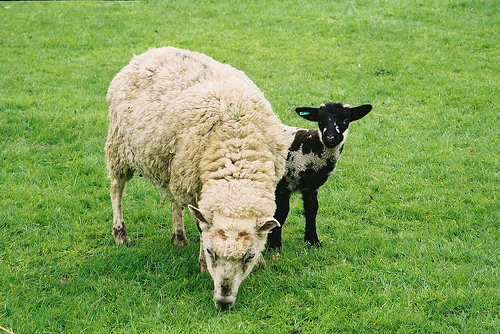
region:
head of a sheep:
[169, 191, 289, 322]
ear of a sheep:
[175, 185, 213, 231]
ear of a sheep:
[239, 204, 296, 241]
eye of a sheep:
[193, 240, 216, 267]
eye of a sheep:
[240, 242, 260, 260]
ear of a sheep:
[291, 107, 318, 129]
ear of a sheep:
[354, 96, 374, 121]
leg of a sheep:
[250, 178, 307, 260]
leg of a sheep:
[93, 181, 147, 258]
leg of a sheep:
[294, 187, 329, 247]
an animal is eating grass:
[93, 42, 293, 316]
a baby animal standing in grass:
[261, 91, 383, 265]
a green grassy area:
[373, 10, 490, 332]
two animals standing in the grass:
[93, 43, 375, 318]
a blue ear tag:
[294, 107, 311, 118]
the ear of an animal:
[349, 98, 374, 123]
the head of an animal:
[186, 197, 290, 313]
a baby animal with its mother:
[90, 41, 373, 315]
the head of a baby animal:
[291, 94, 374, 147]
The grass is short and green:
[376, 35, 481, 304]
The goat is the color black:
[287, 73, 375, 260]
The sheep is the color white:
[87, 38, 292, 310]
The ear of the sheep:
[181, 199, 216, 230]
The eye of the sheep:
[199, 242, 224, 264]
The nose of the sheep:
[210, 291, 240, 312]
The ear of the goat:
[295, 99, 322, 124]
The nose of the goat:
[321, 128, 338, 146]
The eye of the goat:
[339, 113, 352, 130]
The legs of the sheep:
[101, 178, 188, 252]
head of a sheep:
[166, 185, 301, 312]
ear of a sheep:
[188, 201, 225, 229]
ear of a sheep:
[246, 204, 294, 244]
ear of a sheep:
[280, 93, 327, 160]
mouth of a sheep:
[314, 124, 342, 151]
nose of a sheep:
[211, 265, 256, 291]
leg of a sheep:
[163, 179, 205, 245]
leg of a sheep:
[258, 188, 294, 262]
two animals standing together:
[97, 35, 372, 320]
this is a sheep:
[85, 36, 300, 311]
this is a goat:
[266, 65, 371, 232]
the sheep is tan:
[88, 21, 311, 319]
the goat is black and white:
[255, 79, 389, 266]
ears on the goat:
[299, 94, 363, 125]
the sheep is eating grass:
[148, 67, 283, 328]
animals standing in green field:
[14, 8, 462, 328]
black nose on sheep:
[209, 278, 244, 310]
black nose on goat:
[322, 119, 339, 154]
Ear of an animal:
[293, 104, 318, 126]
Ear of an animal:
[353, 99, 375, 124]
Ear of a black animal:
[294, 102, 316, 124]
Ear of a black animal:
[351, 100, 375, 122]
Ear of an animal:
[186, 205, 213, 229]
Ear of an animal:
[256, 215, 286, 232]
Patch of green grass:
[367, 205, 478, 316]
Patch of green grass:
[403, 61, 475, 146]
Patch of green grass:
[388, 26, 470, 97]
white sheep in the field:
[91, 37, 293, 298]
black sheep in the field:
[263, 72, 368, 248]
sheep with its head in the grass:
[181, 187, 284, 328]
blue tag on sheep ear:
[292, 104, 312, 121]